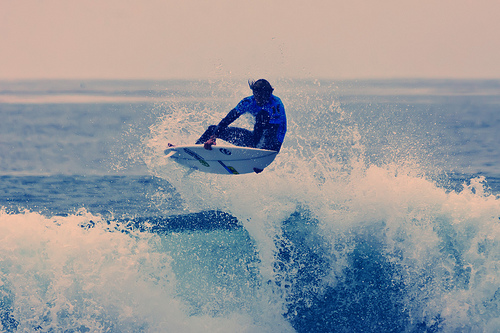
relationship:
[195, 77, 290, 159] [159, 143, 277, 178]
man on a surfboard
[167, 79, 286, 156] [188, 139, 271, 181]
man holding surfboard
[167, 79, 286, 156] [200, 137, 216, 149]
man has hand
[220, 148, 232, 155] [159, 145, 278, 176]
symbol on board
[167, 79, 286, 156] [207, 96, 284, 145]
man wearing wet suit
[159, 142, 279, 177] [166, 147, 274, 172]
board has base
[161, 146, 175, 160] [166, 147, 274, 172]
fin on base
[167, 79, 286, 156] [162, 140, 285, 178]
man holding surfboard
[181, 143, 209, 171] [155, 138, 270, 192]
fin on surfboard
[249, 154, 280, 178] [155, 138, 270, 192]
fin on surfboard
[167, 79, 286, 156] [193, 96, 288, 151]
man wearing wet suit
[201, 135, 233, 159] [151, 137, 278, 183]
hand gripping surfboard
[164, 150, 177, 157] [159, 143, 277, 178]
fin on surfboard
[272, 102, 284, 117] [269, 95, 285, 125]
logo on shoulder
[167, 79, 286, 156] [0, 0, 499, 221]
man in air